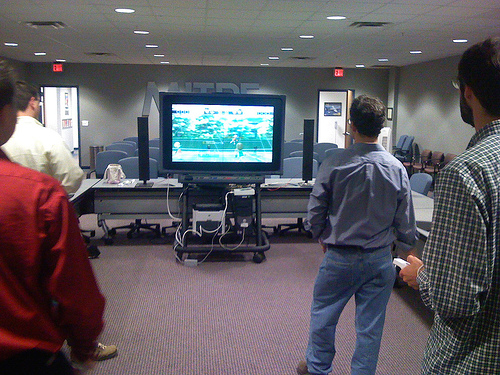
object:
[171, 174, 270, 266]
cart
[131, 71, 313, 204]
tv set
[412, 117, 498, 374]
shirt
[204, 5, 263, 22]
ceiling tile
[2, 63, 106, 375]
man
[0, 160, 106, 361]
red shirt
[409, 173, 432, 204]
chair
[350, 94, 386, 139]
hair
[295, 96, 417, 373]
man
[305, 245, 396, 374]
jeans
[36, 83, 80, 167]
door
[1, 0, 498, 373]
room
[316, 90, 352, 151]
open doorway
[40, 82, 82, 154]
open doorway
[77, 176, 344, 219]
desk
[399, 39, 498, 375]
man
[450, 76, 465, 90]
glasses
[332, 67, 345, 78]
sign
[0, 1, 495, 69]
ceiling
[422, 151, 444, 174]
chair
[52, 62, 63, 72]
sign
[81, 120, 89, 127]
light switch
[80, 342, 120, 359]
shoe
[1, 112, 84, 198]
shirt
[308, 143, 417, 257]
shirt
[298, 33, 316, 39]
ceiling light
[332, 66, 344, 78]
exit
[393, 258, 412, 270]
controler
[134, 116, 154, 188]
speaker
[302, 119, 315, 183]
speaker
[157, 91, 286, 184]
computer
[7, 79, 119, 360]
man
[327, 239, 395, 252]
belt